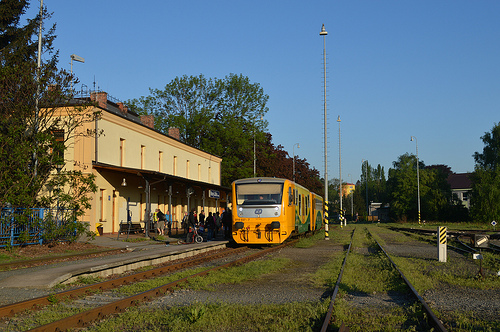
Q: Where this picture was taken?
A: In a platform.